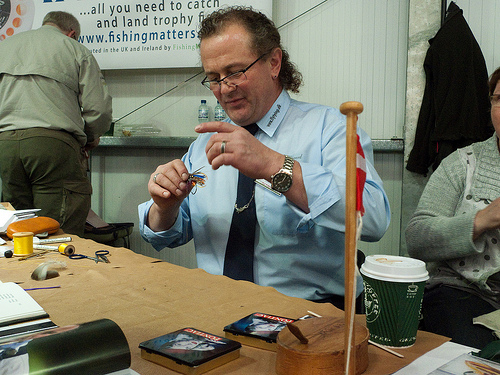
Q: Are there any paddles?
A: No, there are no paddles.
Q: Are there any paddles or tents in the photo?
A: No, there are no paddles or tents.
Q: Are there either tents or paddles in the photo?
A: No, there are no paddles or tents.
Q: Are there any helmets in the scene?
A: No, there are no helmets.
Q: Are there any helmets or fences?
A: No, there are no helmets or fences.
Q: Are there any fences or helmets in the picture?
A: No, there are no helmets or fences.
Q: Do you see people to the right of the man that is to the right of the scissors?
A: Yes, there is a person to the right of the man.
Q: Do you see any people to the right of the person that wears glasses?
A: Yes, there is a person to the right of the man.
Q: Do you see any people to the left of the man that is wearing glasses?
A: No, the person is to the right of the man.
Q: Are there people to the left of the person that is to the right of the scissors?
A: No, the person is to the right of the man.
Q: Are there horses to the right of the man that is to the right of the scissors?
A: No, there is a person to the right of the man.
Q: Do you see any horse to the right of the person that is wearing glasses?
A: No, there is a person to the right of the man.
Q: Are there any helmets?
A: No, there are no helmets.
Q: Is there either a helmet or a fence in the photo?
A: No, there are no helmets or fences.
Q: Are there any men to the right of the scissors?
A: Yes, there is a man to the right of the scissors.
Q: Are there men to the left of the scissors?
A: No, the man is to the right of the scissors.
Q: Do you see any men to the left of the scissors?
A: No, the man is to the right of the scissors.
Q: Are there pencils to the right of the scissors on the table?
A: No, there is a man to the right of the scissors.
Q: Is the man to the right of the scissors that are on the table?
A: Yes, the man is to the right of the scissors.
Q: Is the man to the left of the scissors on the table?
A: No, the man is to the right of the scissors.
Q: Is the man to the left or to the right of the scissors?
A: The man is to the right of the scissors.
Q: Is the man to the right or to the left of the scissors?
A: The man is to the right of the scissors.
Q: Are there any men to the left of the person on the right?
A: Yes, there is a man to the left of the person.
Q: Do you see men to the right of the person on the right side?
A: No, the man is to the left of the person.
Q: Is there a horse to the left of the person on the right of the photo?
A: No, there is a man to the left of the person.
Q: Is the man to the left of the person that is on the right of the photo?
A: Yes, the man is to the left of the person.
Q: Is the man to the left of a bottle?
A: No, the man is to the left of the person.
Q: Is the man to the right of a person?
A: No, the man is to the left of a person.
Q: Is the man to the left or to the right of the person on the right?
A: The man is to the left of the person.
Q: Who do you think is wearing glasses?
A: The man is wearing glasses.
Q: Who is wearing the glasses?
A: The man is wearing glasses.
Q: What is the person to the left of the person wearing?
A: The man is wearing glasses.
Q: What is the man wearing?
A: The man is wearing glasses.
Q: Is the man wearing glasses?
A: Yes, the man is wearing glasses.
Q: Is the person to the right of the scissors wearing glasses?
A: Yes, the man is wearing glasses.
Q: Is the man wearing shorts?
A: No, the man is wearing glasses.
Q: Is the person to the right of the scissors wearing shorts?
A: No, the man is wearing glasses.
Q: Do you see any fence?
A: No, there are no fences.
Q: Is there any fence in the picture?
A: No, there are no fences.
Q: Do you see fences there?
A: No, there are no fences.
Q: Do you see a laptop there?
A: No, there are no laptops.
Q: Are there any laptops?
A: No, there are no laptops.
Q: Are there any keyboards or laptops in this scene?
A: No, there are no laptops or keyboards.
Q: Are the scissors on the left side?
A: Yes, the scissors are on the left of the image.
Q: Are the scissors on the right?
A: No, the scissors are on the left of the image.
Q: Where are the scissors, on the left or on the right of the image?
A: The scissors are on the left of the image.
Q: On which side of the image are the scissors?
A: The scissors are on the left of the image.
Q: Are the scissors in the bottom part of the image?
A: Yes, the scissors are in the bottom of the image.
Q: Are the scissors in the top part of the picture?
A: No, the scissors are in the bottom of the image.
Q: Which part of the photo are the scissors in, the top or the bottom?
A: The scissors are in the bottom of the image.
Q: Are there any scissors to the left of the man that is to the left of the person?
A: Yes, there are scissors to the left of the man.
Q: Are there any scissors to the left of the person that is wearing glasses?
A: Yes, there are scissors to the left of the man.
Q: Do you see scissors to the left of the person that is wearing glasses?
A: Yes, there are scissors to the left of the man.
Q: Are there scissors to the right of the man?
A: No, the scissors are to the left of the man.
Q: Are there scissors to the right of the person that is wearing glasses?
A: No, the scissors are to the left of the man.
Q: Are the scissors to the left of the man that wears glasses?
A: Yes, the scissors are to the left of the man.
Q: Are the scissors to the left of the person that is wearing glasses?
A: Yes, the scissors are to the left of the man.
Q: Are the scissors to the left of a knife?
A: No, the scissors are to the left of the man.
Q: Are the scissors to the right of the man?
A: No, the scissors are to the left of the man.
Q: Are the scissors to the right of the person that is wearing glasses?
A: No, the scissors are to the left of the man.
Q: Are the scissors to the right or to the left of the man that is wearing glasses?
A: The scissors are to the left of the man.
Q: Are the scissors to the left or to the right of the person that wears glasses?
A: The scissors are to the left of the man.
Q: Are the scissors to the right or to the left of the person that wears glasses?
A: The scissors are to the left of the man.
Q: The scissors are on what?
A: The scissors are on the table.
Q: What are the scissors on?
A: The scissors are on the table.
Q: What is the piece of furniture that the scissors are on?
A: The piece of furniture is a table.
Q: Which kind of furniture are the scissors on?
A: The scissors are on the table.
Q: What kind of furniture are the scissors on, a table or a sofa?
A: The scissors are on a table.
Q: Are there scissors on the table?
A: Yes, there are scissors on the table.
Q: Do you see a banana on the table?
A: No, there are scissors on the table.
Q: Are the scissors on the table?
A: Yes, the scissors are on the table.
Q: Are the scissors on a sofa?
A: No, the scissors are on the table.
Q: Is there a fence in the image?
A: No, there are no fences.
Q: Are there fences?
A: No, there are no fences.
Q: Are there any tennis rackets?
A: No, there are no tennis rackets.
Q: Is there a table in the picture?
A: Yes, there is a table.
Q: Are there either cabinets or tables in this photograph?
A: Yes, there is a table.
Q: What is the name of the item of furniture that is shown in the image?
A: The piece of furniture is a table.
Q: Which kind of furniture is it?
A: The piece of furniture is a table.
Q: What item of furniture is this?
A: This is a table.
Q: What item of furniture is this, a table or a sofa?
A: This is a table.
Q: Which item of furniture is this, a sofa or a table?
A: This is a table.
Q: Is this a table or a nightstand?
A: This is a table.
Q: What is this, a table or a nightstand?
A: This is a table.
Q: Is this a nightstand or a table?
A: This is a table.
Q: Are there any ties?
A: Yes, there is a tie.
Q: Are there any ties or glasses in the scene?
A: Yes, there is a tie.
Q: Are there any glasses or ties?
A: Yes, there is a tie.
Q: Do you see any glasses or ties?
A: Yes, there is a tie.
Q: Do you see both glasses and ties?
A: Yes, there are both a tie and glasses.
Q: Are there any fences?
A: No, there are no fences.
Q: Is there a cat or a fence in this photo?
A: No, there are no fences or cats.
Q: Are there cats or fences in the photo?
A: No, there are no fences or cats.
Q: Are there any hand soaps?
A: No, there are no hand soaps.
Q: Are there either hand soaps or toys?
A: No, there are no hand soaps or toys.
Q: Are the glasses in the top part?
A: Yes, the glasses are in the top of the image.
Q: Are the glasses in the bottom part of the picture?
A: No, the glasses are in the top of the image.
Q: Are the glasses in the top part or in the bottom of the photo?
A: The glasses are in the top of the image.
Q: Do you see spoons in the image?
A: No, there are no spoons.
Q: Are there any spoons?
A: No, there are no spoons.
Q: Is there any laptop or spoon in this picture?
A: No, there are no spoons or laptops.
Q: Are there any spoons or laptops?
A: No, there are no spoons or laptops.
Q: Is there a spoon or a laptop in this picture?
A: No, there are no spoons or laptops.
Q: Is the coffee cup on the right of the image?
A: Yes, the coffee cup is on the right of the image.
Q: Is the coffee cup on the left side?
A: No, the coffee cup is on the right of the image.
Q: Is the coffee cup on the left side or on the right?
A: The coffee cup is on the right of the image.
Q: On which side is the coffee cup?
A: The coffee cup is on the right of the image.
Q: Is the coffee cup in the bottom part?
A: Yes, the coffee cup is in the bottom of the image.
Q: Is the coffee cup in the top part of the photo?
A: No, the coffee cup is in the bottom of the image.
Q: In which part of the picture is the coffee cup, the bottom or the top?
A: The coffee cup is in the bottom of the image.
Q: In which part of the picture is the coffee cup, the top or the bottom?
A: The coffee cup is in the bottom of the image.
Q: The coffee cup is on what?
A: The coffee cup is on the table.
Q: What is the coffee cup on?
A: The coffee cup is on the table.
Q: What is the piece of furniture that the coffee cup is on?
A: The piece of furniture is a table.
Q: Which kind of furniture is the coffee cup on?
A: The coffee cup is on the table.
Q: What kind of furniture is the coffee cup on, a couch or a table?
A: The coffee cup is on a table.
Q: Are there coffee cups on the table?
A: Yes, there is a coffee cup on the table.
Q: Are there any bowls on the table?
A: No, there is a coffee cup on the table.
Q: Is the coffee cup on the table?
A: Yes, the coffee cup is on the table.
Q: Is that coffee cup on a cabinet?
A: No, the coffee cup is on the table.